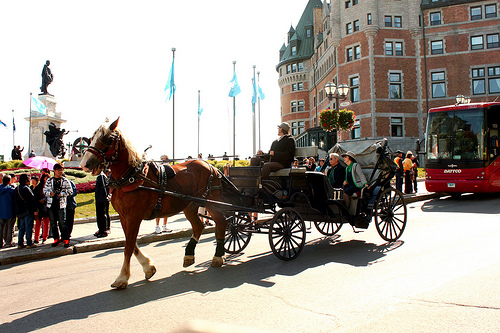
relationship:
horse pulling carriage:
[76, 112, 239, 291] [259, 157, 399, 243]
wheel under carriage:
[267, 203, 319, 267] [246, 101, 423, 266]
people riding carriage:
[258, 124, 367, 192] [233, 137, 411, 258]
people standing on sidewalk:
[50, 165, 69, 247] [2, 222, 194, 248]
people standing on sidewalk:
[42, 163, 73, 248] [2, 222, 194, 248]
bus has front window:
[416, 95, 498, 199] [424, 104, 499, 170]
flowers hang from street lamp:
[317, 106, 355, 133] [320, 75, 350, 141]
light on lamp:
[431, 71, 445, 93] [323, 83, 353, 158]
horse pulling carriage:
[57, 105, 269, 288] [209, 123, 414, 261]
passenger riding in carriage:
[323, 152, 343, 192] [217, 135, 412, 265]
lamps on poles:
[340, 110, 353, 126] [335, 45, 340, 145]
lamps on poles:
[318, 109, 335, 127] [335, 45, 340, 145]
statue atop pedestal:
[37, 57, 57, 98] [26, 92, 65, 164]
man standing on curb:
[42, 161, 76, 246] [1, 192, 433, 271]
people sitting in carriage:
[327, 152, 369, 195] [222, 135, 407, 252]